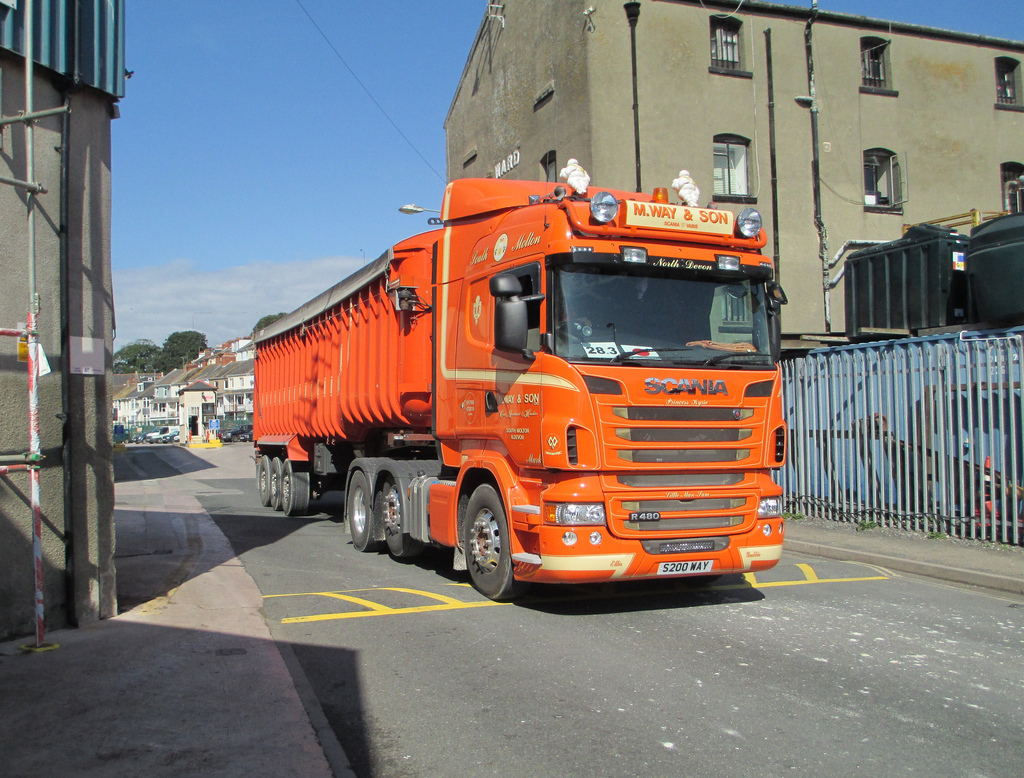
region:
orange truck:
[187, 151, 810, 642]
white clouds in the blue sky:
[157, 215, 195, 244]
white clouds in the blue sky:
[266, 124, 315, 191]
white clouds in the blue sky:
[160, 212, 236, 279]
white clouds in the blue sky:
[198, 230, 256, 273]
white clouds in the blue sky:
[289, 122, 344, 183]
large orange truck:
[218, 145, 765, 639]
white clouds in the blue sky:
[200, 94, 252, 133]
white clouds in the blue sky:
[176, 268, 218, 287]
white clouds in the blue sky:
[230, 133, 288, 209]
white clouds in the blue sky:
[180, 274, 216, 293]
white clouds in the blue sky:
[236, 117, 306, 197]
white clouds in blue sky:
[172, 212, 259, 264]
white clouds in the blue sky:
[231, 192, 283, 250]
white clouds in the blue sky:
[169, 22, 277, 83]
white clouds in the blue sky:
[204, 247, 280, 293]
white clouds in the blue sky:
[146, 186, 219, 267]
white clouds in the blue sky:
[222, 253, 268, 302]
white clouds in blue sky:
[214, 276, 285, 331]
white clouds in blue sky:
[97, 261, 180, 318]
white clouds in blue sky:
[264, 192, 337, 265]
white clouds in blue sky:
[189, 122, 266, 199]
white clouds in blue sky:
[190, 243, 252, 291]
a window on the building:
[861, 112, 915, 192]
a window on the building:
[851, 22, 903, 89]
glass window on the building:
[702, 14, 738, 72]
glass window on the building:
[702, 137, 756, 192]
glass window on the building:
[868, 157, 894, 203]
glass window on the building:
[991, 52, 1015, 98]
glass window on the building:
[1002, 163, 1019, 214]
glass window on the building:
[541, 156, 554, 185]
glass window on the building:
[232, 390, 242, 404]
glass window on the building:
[152, 397, 168, 418]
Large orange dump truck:
[249, 170, 803, 607]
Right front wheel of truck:
[446, 467, 529, 595]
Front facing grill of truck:
[603, 394, 760, 538]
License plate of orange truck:
[651, 551, 725, 578]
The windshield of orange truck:
[537, 251, 787, 360]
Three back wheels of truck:
[241, 444, 317, 515]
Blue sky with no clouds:
[145, 31, 441, 237]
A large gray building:
[439, 18, 1005, 348]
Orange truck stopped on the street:
[219, 178, 824, 611]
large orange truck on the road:
[255, 168, 778, 609]